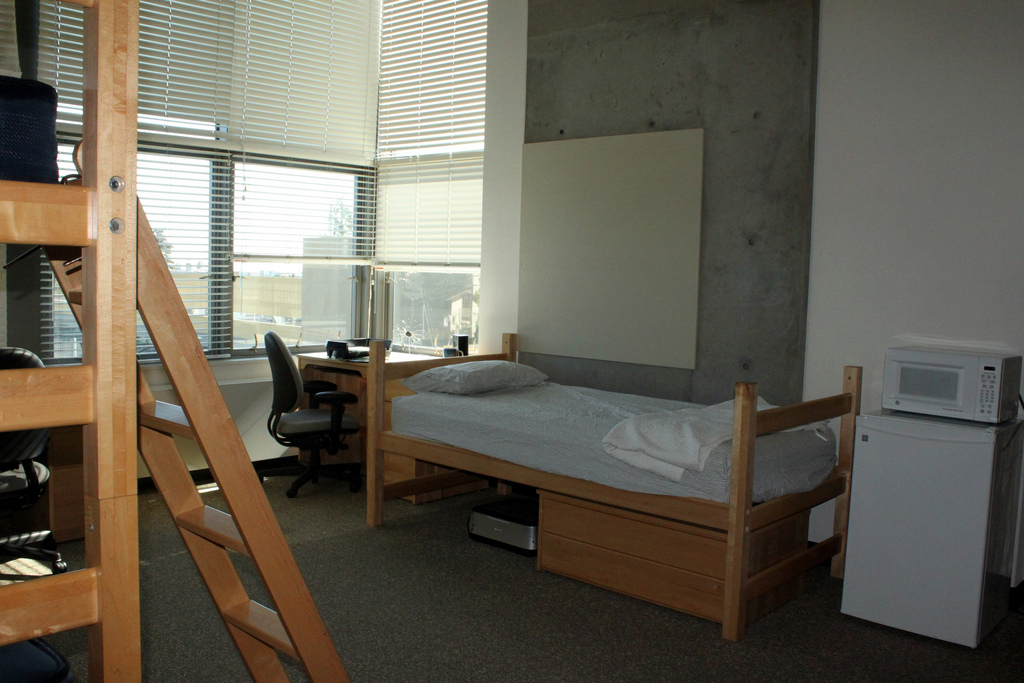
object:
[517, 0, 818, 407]
wall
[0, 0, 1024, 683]
building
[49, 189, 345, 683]
stairs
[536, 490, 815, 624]
drawer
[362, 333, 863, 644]
bed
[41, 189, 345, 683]
ladder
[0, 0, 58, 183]
bunk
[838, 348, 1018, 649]
fridge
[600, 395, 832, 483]
sheet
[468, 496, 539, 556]
object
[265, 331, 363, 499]
chair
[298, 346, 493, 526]
desk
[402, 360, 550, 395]
pillow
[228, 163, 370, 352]
window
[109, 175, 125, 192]
bolt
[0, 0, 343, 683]
bed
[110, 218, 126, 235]
bolt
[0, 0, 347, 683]
wood